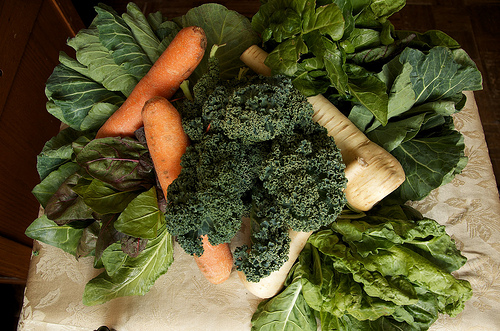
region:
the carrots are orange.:
[95, 25, 238, 290]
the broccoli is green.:
[155, 76, 348, 276]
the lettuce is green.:
[24, 2, 481, 324]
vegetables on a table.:
[38, 1, 470, 329]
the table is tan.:
[9, 72, 499, 320]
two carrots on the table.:
[85, 19, 231, 283]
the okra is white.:
[220, 40, 402, 306]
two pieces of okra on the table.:
[217, 39, 407, 299]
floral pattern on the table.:
[16, 57, 496, 329]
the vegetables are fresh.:
[21, 1, 484, 323]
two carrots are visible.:
[88, 14, 243, 285]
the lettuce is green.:
[50, 10, 482, 330]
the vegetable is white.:
[238, 38, 398, 215]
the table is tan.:
[19, 29, 499, 324]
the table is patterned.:
[19, 25, 499, 322]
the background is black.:
[1, 2, 491, 320]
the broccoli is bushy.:
[152, 64, 346, 276]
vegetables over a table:
[31, 1, 496, 329]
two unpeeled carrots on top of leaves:
[106, 10, 238, 300]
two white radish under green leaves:
[243, 44, 418, 301]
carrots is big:
[129, 91, 237, 283]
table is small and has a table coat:
[20, 20, 496, 326]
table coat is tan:
[14, 28, 496, 328]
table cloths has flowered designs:
[24, 288, 231, 330]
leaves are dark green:
[160, 73, 362, 283]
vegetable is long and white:
[239, 42, 408, 212]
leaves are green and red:
[28, 134, 167, 316]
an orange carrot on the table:
[89, 21, 208, 142]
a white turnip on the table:
[239, 42, 413, 218]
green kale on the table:
[157, 66, 355, 289]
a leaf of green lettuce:
[250, 275, 312, 329]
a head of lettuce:
[250, 212, 472, 329]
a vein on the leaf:
[216, 11, 229, 41]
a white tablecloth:
[12, 86, 498, 328]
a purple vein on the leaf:
[109, 151, 145, 167]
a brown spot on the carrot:
[195, 34, 210, 53]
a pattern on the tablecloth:
[443, 192, 498, 242]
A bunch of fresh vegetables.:
[6, 8, 493, 323]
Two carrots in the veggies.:
[118, 0, 236, 281]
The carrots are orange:
[80, 20, 241, 280]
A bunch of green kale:
[150, 63, 353, 292]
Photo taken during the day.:
[0, 13, 492, 324]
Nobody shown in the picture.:
[11, 14, 495, 324]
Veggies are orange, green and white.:
[33, 0, 485, 321]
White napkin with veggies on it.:
[19, 40, 471, 325]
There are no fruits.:
[27, 2, 492, 323]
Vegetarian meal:
[17, 0, 494, 322]